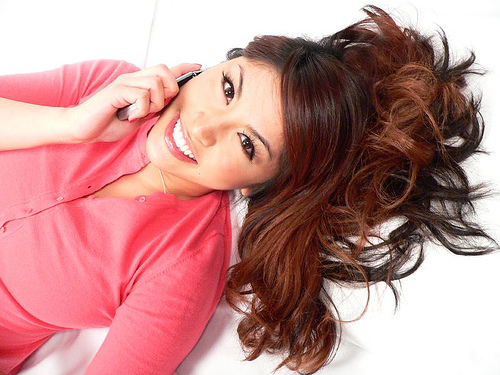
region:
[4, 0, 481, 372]
woman with long, auburn hair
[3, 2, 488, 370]
long haired woman talking on cell phone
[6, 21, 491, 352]
woman with brown eyes smiling at camera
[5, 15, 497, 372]
woman's hair spread out on bed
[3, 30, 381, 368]
woman wearing salmon colored shirt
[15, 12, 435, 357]
woman wearing salmon button down shirt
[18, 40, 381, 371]
woman with thin eyebrows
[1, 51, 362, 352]
woman wearing light pink lipgloss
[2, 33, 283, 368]
woman with long, full eyelashes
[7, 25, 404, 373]
top button of shirt unbuttoned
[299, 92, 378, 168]
the womens hair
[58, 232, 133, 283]
a pink shirt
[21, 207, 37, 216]
a button on the shirt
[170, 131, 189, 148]
the womens teeth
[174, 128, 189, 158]
the teeth are white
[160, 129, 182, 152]
bottom lip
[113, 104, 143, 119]
the women is holding a phone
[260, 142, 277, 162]
the womens eyebrows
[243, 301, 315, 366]
brown hair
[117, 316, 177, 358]
sleeve on the shirt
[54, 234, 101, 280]
pink shirt on a woman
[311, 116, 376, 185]
brown hair on a woman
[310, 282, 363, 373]
shadow from a woman's hair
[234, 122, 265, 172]
dark eye of a woman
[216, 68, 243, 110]
dark eye of a woman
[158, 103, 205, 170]
lipstick on a woman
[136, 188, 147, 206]
button on a sweater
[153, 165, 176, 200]
necklace on a neck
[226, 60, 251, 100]
eyebrow on a woman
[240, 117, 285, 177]
eyebrow on a woman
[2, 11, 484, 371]
she is smiling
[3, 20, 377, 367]
she is talking on the phone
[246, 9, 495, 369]
she has a beautiful hair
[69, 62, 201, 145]
her hand holding the phone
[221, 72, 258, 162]
the eyes of the girl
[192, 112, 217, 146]
the nose of the woman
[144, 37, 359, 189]
the head of the woman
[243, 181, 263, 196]
one ear of the girl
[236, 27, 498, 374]
her hair is dark brown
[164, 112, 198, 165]
her lips are red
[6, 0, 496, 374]
lady wearing a pink shirt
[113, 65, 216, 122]
silver and black plastic flip phone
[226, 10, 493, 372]
long reddish brown hair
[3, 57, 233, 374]
pink button up shirt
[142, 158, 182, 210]
thin white necklace cord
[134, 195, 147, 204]
small shiny pink button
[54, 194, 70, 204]
small shiny pink button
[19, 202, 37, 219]
small shiny pink button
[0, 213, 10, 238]
small shiny pink button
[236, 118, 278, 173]
woman's left eye ball